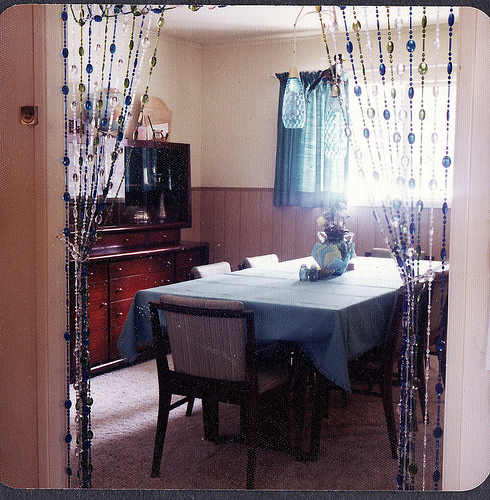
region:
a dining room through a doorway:
[25, 5, 475, 492]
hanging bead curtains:
[53, 3, 454, 493]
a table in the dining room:
[138, 224, 448, 470]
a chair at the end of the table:
[140, 289, 310, 494]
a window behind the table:
[266, 67, 464, 222]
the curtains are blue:
[267, 69, 356, 213]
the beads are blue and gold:
[57, 2, 453, 493]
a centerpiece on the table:
[301, 196, 357, 283]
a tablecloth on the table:
[117, 244, 445, 391]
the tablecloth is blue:
[123, 244, 451, 398]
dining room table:
[126, 220, 446, 474]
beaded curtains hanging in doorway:
[58, 3, 441, 497]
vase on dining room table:
[312, 210, 353, 272]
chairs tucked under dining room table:
[154, 234, 440, 471]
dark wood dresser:
[69, 210, 208, 370]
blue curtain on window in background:
[268, 71, 350, 214]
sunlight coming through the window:
[341, 89, 447, 196]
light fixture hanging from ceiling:
[280, 19, 311, 133]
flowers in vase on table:
[313, 201, 348, 241]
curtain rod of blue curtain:
[276, 68, 340, 76]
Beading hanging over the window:
[38, 66, 129, 490]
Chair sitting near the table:
[138, 285, 298, 458]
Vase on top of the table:
[297, 206, 372, 286]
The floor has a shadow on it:
[111, 431, 185, 495]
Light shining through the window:
[272, 89, 477, 217]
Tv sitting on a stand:
[112, 126, 206, 225]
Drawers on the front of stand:
[86, 264, 188, 362]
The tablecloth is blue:
[208, 262, 315, 332]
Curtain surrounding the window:
[273, 99, 347, 180]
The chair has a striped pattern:
[158, 295, 258, 379]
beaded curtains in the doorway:
[64, 10, 449, 495]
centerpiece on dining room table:
[312, 194, 355, 276]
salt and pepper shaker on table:
[297, 264, 317, 282]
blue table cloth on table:
[120, 258, 446, 386]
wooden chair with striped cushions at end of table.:
[149, 298, 295, 489]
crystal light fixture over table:
[284, 61, 303, 126]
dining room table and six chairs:
[140, 242, 447, 477]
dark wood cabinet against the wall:
[74, 232, 205, 375]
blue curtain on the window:
[266, 70, 349, 212]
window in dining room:
[268, 72, 447, 207]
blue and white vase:
[315, 242, 355, 273]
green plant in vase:
[319, 198, 354, 244]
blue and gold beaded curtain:
[315, 8, 459, 490]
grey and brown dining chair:
[148, 298, 283, 484]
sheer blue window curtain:
[280, 75, 347, 208]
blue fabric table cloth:
[124, 250, 434, 368]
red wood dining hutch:
[77, 246, 204, 370]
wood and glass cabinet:
[71, 137, 192, 249]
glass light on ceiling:
[285, 75, 303, 128]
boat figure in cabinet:
[157, 194, 165, 221]